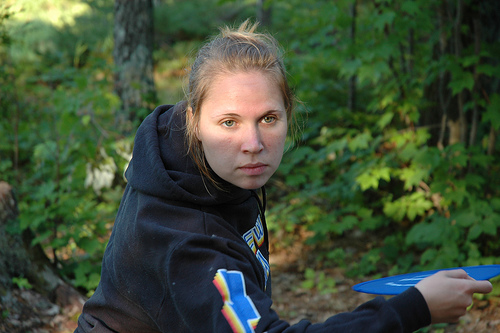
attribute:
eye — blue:
[220, 119, 239, 129]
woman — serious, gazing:
[76, 23, 493, 332]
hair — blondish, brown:
[183, 17, 312, 203]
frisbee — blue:
[351, 263, 499, 296]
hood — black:
[123, 103, 245, 206]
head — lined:
[183, 29, 291, 193]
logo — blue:
[212, 268, 261, 332]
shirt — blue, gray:
[74, 101, 433, 331]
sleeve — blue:
[166, 234, 430, 333]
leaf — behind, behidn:
[358, 176, 380, 194]